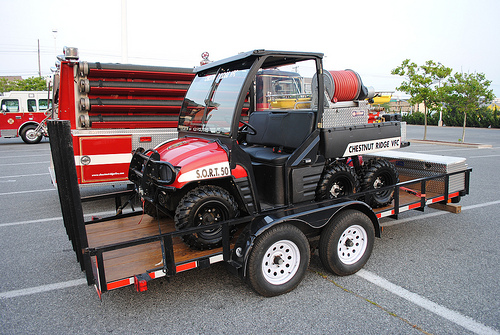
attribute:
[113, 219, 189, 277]
rail — black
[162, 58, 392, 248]
atv — black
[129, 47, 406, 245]
car — small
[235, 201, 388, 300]
wheels — black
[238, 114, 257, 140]
steering wheel — black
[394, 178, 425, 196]
tie — red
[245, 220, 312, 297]
tires — black, round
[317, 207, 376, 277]
tires — round, black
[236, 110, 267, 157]
seat — unripped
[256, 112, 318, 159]
seat — unripped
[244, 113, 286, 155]
seat — unripped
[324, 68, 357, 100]
cable — red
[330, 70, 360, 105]
rope roll — red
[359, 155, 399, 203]
wheel — small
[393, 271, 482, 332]
line — white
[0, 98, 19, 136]
door — to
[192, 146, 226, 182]
writing — black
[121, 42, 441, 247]
atv — red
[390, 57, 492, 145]
trees — green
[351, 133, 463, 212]
toolbox — diamond plated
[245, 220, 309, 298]
wheel — on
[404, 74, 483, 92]
leaves — green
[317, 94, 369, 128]
toolbox — silver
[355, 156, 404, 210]
wheel — rear